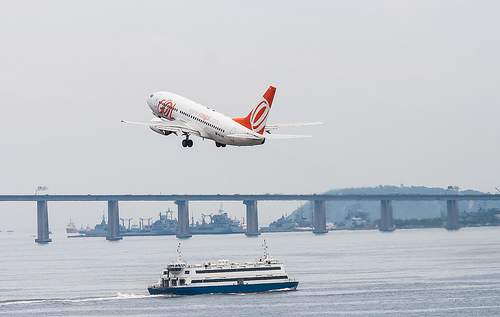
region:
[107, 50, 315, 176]
a red and white plane in the sky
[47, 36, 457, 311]
a plane flying over a ship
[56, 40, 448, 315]
a commercial plane taking off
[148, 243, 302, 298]
a blue and white ship sailing in the river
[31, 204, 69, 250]
a large cement column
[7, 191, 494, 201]
a long cement bridge over the river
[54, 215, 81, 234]
a red ship in the distance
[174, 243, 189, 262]
antenna on the ship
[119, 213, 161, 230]
windmills in the distance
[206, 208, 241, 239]
a large ship docked on the other side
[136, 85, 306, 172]
plane in overcast sky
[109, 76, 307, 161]
plane with orange and white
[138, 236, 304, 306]
boat cruising in water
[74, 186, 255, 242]
ships in water behind bridge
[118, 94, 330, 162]
wheels on plane down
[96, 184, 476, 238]
long bridge over water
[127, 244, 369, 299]
boat is white and blue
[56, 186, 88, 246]
ship cruising toward bridge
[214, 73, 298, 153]
orange tail on plane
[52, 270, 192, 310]
wake water behind boat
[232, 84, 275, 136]
red tail of airplane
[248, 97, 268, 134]
white logo on airplane tail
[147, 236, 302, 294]
white boat under airplane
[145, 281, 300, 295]
bottom of boat is blue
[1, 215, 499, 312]
boat is in the water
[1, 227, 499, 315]
water is calm and gray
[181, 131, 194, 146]
two black wheels under airplane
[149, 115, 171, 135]
engine on wing of airplane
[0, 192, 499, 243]
gray bridge under airplane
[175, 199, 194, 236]
pylon under bridge deck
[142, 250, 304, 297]
A large white and blue boat on the water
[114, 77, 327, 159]
A large white and red plane taking off above the boat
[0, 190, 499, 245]
A dark bridge crossing the water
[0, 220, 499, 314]
The water with gentle waves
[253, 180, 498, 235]
A hill behind the bridge in the distance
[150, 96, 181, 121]
A red logo on the plane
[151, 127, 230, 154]
The landing and take-off gear of the plane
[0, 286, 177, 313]
The wake of the boat on the water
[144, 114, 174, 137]
A white jet engine on the plane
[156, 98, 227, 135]
Windows along the length of the plane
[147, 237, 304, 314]
A white and blue boat.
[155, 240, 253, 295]
A white and blue boat.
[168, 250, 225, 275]
A white and blue boat.